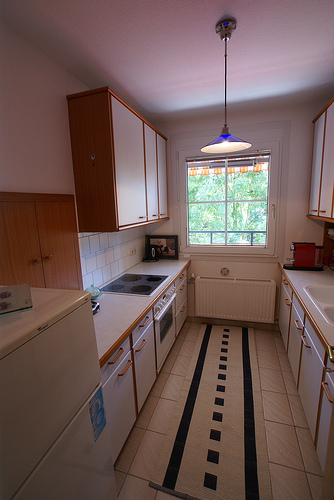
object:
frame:
[145, 235, 178, 261]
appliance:
[283, 241, 326, 271]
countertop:
[286, 262, 333, 345]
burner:
[130, 285, 152, 293]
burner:
[146, 277, 161, 282]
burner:
[122, 275, 142, 282]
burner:
[108, 284, 125, 290]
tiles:
[262, 390, 294, 426]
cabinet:
[95, 293, 154, 412]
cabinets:
[66, 85, 146, 232]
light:
[200, 12, 253, 154]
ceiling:
[0, 0, 333, 125]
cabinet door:
[108, 88, 146, 232]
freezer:
[0, 287, 119, 500]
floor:
[120, 323, 322, 497]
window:
[185, 150, 272, 249]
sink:
[324, 306, 334, 326]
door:
[288, 304, 303, 388]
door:
[299, 317, 326, 443]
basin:
[308, 285, 333, 305]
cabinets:
[144, 119, 157, 222]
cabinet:
[1, 191, 83, 291]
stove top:
[100, 274, 168, 295]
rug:
[148, 321, 272, 498]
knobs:
[139, 217, 144, 219]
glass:
[85, 284, 100, 298]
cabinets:
[157, 135, 173, 219]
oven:
[151, 275, 177, 369]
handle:
[135, 339, 147, 352]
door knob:
[47, 255, 53, 261]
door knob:
[37, 257, 42, 264]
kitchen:
[0, 0, 332, 498]